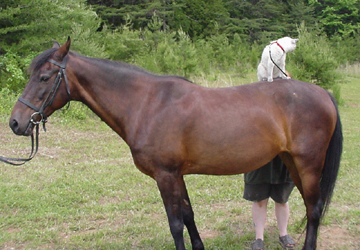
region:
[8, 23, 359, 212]
A brown horse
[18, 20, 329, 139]
A white cat on a brown horse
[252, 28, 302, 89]
A white cat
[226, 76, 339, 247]
A person standing behind a horse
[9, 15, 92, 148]
The head of a brown horse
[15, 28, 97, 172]
The head of a horse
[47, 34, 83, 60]
The ear of a brown horse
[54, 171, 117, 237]
Grass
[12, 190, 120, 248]
Green grass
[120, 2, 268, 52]
Green trees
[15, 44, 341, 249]
the horse is facing left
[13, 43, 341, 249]
the horse is standing still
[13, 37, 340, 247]
the horse is brown in color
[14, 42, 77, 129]
the horse is wearing a harness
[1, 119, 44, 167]
the horse is held by a leash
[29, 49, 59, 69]
the horse has long hair on top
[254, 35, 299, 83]
a cat is on top of the horse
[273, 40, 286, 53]
the cat is wearing a collar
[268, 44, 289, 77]
the cat has a leash on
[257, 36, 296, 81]
the cat is white in color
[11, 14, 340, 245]
a large horse standing in the grass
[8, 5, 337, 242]
a person is obscured by a large brown horse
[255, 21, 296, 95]
a small dog is seated on the hind quarters of a horse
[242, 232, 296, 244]
person is wearing sandals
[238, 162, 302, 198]
person is wearing a pair of shorts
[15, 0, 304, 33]
trees growing in the background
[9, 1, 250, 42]
vegetation growing in the background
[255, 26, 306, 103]
a small dog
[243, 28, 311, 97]
a white puppy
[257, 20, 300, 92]
a dog with a red collar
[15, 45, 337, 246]
horse is large and brown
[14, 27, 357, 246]
a horse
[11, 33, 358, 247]
a brown horse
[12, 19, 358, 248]
a cat sits on a horse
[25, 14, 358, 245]
a white cat sits on a horse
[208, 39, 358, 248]
a person stands behind the horse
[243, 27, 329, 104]
a white cat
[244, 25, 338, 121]
the white cat is looking at the person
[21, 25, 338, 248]
the horse stands in a field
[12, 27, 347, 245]
the horse is wearing a bridal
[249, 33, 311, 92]
the cat is wearing a leach